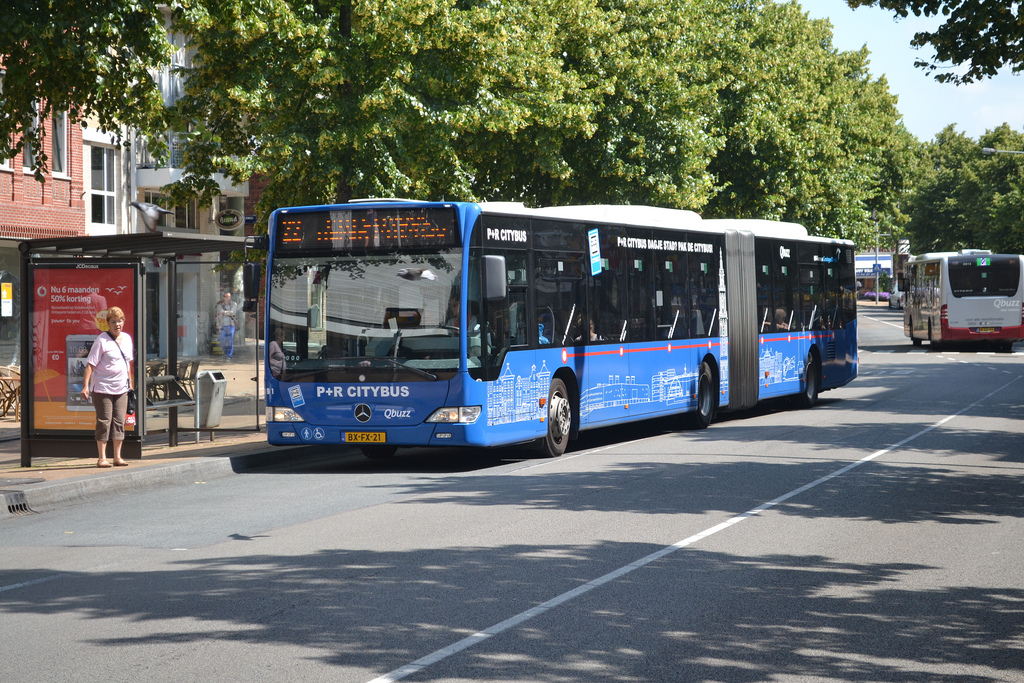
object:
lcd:
[309, 216, 448, 242]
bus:
[243, 196, 859, 457]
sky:
[799, 0, 1020, 146]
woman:
[80, 305, 135, 467]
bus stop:
[14, 230, 261, 467]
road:
[2, 308, 1024, 683]